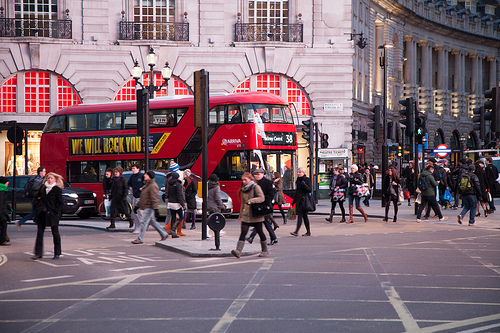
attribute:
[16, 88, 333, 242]
red bus — double decker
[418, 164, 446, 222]
man — walking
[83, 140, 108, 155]
word — will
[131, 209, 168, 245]
jeans — blue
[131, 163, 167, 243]
man — wearing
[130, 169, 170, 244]
man — wearing, walking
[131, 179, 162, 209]
jacket — brown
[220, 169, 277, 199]
scarf — white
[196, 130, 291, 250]
woman — wearing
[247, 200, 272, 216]
purse — black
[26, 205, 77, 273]
pants — black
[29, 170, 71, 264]
woman — wearing